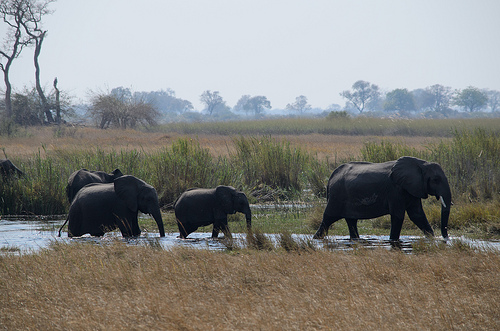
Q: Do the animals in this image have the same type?
A: Yes, all the animals are elephants.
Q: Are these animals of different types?
A: No, all the animals are elephants.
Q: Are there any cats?
A: No, there are no cats.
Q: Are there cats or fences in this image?
A: No, there are no cats or fences.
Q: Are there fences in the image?
A: No, there are no fences.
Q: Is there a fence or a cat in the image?
A: No, there are no fences or cats.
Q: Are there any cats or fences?
A: No, there are no fences or cats.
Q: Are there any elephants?
A: Yes, there is an elephant.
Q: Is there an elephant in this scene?
A: Yes, there is an elephant.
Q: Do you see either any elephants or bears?
A: Yes, there is an elephant.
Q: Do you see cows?
A: No, there are no cows.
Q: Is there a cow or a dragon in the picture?
A: No, there are no cows or dragons.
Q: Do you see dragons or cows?
A: No, there are no cows or dragons.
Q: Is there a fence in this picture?
A: No, there are no fences.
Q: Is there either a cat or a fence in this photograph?
A: No, there are no fences or cats.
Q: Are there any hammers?
A: No, there are no hammers.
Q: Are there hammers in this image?
A: No, there are no hammers.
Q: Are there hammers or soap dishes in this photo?
A: No, there are no hammers or soap dishes.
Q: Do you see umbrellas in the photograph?
A: No, there are no umbrellas.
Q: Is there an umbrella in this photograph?
A: No, there are no umbrellas.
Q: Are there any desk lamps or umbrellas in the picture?
A: No, there are no umbrellas or desk lamps.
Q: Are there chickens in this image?
A: No, there are no chickens.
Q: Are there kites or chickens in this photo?
A: No, there are no chickens or kites.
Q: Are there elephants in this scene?
A: Yes, there are elephants.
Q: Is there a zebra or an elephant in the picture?
A: Yes, there are elephants.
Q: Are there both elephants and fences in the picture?
A: No, there are elephants but no fences.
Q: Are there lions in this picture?
A: No, there are no lions.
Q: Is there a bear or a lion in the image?
A: No, there are no lions or bears.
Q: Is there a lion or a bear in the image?
A: No, there are no lions or bears.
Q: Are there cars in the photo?
A: No, there are no cars.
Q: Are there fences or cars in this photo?
A: No, there are no cars or fences.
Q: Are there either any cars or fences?
A: No, there are no cars or fences.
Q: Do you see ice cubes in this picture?
A: No, there are no ice cubes.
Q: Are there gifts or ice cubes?
A: No, there are no ice cubes or gifts.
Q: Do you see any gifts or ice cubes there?
A: No, there are no ice cubes or gifts.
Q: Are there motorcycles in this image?
A: No, there are no motorcycles.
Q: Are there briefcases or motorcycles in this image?
A: No, there are no motorcycles or briefcases.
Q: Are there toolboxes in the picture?
A: No, there are no toolboxes.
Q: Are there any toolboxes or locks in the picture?
A: No, there are no toolboxes or locks.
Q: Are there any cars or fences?
A: No, there are no fences or cars.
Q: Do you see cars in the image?
A: No, there are no cars.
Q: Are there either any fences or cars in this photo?
A: No, there are no cars or fences.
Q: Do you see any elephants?
A: Yes, there is an elephant.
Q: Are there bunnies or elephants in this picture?
A: Yes, there is an elephant.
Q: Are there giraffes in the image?
A: No, there are no giraffes.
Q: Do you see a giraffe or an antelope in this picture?
A: No, there are no giraffes or antelopes.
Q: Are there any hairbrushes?
A: No, there are no hairbrushes.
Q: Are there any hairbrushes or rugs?
A: No, there are no hairbrushes or rugs.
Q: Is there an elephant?
A: Yes, there are elephants.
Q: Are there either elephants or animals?
A: Yes, there are elephants.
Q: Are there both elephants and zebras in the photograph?
A: No, there are elephants but no zebras.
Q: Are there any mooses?
A: No, there are no mooses.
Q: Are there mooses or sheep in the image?
A: No, there are no mooses or sheep.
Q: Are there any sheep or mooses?
A: No, there are no mooses or sheep.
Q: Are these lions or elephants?
A: These are elephants.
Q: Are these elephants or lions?
A: These are elephants.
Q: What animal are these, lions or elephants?
A: These are elephants.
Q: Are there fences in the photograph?
A: No, there are no fences.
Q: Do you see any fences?
A: No, there are no fences.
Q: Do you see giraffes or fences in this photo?
A: No, there are no fences or giraffes.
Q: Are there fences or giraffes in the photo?
A: No, there are no fences or giraffes.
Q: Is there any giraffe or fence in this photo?
A: No, there are no fences or giraffes.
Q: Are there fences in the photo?
A: No, there are no fences.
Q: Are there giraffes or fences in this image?
A: No, there are no fences or giraffes.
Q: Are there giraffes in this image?
A: No, there are no giraffes.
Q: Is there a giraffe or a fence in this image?
A: No, there are no giraffes or fences.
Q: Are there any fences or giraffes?
A: No, there are no giraffes or fences.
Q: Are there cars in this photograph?
A: No, there are no cars.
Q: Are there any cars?
A: No, there are no cars.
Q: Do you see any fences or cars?
A: No, there are no cars or fences.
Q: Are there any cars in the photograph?
A: No, there are no cars.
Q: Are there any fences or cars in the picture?
A: No, there are no cars or fences.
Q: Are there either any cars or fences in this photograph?
A: No, there are no cars or fences.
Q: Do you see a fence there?
A: No, there are no fences.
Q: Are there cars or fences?
A: No, there are no fences or cars.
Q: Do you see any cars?
A: No, there are no cars.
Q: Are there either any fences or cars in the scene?
A: No, there are no cars or fences.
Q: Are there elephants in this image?
A: Yes, there is an elephant.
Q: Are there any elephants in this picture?
A: Yes, there is an elephant.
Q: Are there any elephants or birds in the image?
A: Yes, there is an elephant.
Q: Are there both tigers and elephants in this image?
A: No, there is an elephant but no tigers.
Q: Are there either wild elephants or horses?
A: Yes, there is a wild elephant.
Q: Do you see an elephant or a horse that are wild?
A: Yes, the elephant is wild.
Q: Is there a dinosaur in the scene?
A: No, there are no dinosaurs.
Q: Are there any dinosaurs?
A: No, there are no dinosaurs.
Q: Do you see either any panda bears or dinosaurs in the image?
A: No, there are no dinosaurs or panda bears.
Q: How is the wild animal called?
A: The animal is an elephant.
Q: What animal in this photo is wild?
A: The animal is an elephant.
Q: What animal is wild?
A: The animal is an elephant.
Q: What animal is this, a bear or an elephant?
A: This is an elephant.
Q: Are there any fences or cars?
A: No, there are no fences or cars.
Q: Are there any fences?
A: No, there are no fences.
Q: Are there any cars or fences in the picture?
A: No, there are no fences or cars.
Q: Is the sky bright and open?
A: Yes, the sky is bright and open.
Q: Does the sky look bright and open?
A: Yes, the sky is bright and open.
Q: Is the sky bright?
A: Yes, the sky is bright.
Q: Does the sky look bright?
A: Yes, the sky is bright.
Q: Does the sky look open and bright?
A: Yes, the sky is open and bright.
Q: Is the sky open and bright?
A: Yes, the sky is open and bright.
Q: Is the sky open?
A: Yes, the sky is open.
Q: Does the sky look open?
A: Yes, the sky is open.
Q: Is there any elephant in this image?
A: Yes, there is an elephant.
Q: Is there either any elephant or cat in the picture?
A: Yes, there is an elephant.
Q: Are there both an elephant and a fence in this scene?
A: No, there is an elephant but no fences.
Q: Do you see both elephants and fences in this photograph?
A: No, there is an elephant but no fences.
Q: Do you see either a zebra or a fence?
A: No, there are no fences or zebras.